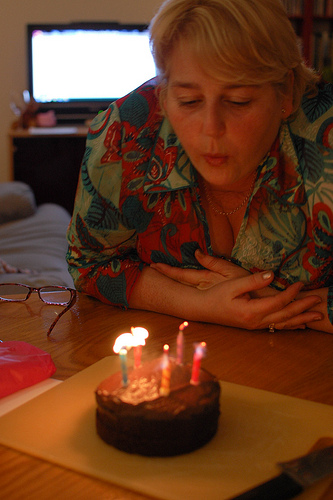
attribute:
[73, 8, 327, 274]
woman — blonde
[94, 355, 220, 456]
birthday cake — small, chocolate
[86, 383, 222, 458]
cake — small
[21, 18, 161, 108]
t.v. — black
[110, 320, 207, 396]
candles — colorful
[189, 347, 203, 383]
red candle — skinny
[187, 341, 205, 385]
candle — birthday candle, half-blown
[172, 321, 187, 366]
candle — birthday candle, half-blown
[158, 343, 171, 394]
candle — half-blown, birthday candle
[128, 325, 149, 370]
candle — half-blown, birthday candle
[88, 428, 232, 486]
paper — red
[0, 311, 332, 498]
table — large, brown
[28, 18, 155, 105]
tv — turned on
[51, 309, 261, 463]
cake — round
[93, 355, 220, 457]
cake — small, round, chocolate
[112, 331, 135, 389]
candle — half-blown, birthday candle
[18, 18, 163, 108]
tv — wide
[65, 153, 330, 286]
shirt — colorful